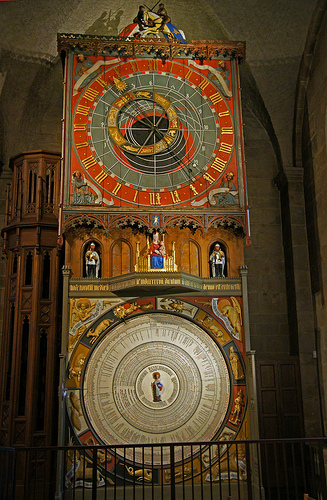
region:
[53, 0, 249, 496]
an antique european clock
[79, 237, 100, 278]
a soldier in a sentry box on a clock face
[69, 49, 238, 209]
a 24 hour clock face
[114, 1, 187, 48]
knights on horseback on top of a vintage clock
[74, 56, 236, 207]
a red and gold clock face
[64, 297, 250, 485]
signs of the zodiac arranged in a circle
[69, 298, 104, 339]
a gold angel decorates an old clock face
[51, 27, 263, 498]
a very ornate detailed clock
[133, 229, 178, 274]
a gilded throne on the front of a clock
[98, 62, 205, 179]
hands with arrows on a clock face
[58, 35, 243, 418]
small clock tower piece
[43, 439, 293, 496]
black metal fence by tower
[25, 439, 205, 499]
black metal bars by tower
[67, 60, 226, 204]
face of the clock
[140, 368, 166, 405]
object in middle of clock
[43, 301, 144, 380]
images around the clock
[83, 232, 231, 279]
small statues on clock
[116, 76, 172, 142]
long hand of clock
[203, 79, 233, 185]
numbers on side of clock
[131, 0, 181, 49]
small figurines on top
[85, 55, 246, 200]
clock on the tower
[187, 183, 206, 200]
number on the clock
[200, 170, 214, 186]
number on the clock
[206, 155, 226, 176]
number on the clock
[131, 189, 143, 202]
number on the clock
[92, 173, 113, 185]
number on the clock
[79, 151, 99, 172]
number on the clock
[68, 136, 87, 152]
number on the clock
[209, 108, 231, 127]
number on the clock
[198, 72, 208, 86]
number on the clock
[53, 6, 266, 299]
A clock behind a gate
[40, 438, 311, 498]
The gate is made of metal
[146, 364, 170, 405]
A woman in the middle of circle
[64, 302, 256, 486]
The zodiac signs on the circle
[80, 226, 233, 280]
Different figurines on display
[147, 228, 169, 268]
The figurine is wearing red and blue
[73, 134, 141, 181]
The clock is red and grey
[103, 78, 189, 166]
The hands on the clock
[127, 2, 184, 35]
The top of the clock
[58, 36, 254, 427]
The clock is made of wood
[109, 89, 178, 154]
The gold ring around the clock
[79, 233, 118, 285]
The small figurine to the left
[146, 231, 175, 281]
The center small figurine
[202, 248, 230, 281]
The small figurine on the rght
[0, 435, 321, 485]
The black fence barrer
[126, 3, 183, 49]
The figurines on top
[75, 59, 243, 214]
The face of the clck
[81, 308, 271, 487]
The silver portion of the clock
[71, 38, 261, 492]
A clock standing behind a fence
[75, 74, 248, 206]
The red ring of the clock